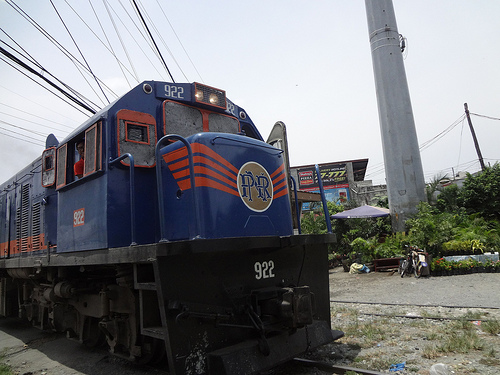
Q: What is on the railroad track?
A: A train.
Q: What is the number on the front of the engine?
A: 922.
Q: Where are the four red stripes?
A: On the front of the engine.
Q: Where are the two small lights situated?
A: Above the windshield of the engine.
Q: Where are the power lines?
A: In the sky.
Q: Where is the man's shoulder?
A: At the window.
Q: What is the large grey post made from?
A: Metal.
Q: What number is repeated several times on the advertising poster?
A: 7.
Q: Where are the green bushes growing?
A: Next to the tracks.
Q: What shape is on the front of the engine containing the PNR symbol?
A: Round.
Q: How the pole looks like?
A: Gray.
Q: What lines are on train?
A: Red lines.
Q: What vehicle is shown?
A: A train.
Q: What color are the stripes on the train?
A: Red.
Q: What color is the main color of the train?
A: Blue.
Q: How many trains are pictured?
A: One.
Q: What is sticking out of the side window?
A: A man in a red shirt.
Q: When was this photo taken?
A: During the daytime.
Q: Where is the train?
A: On the tracks.